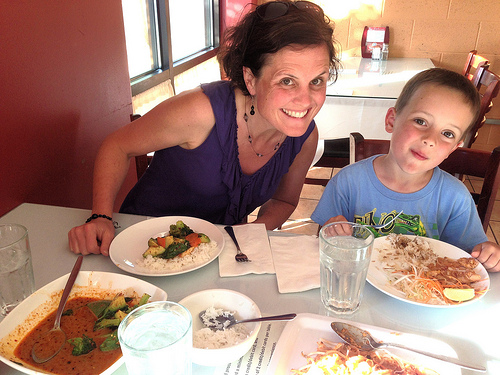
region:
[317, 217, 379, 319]
clear glass with water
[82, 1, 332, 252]
woman wearing purple top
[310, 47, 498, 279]
young boy wearing blue shirt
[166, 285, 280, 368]
white bowl of white rice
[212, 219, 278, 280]
white napkin with fork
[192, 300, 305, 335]
silver spoon with rice on it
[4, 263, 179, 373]
white bowl of green vegetables with sauce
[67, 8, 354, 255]
woman wearing necklace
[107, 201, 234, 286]
white plate with vegetables and rice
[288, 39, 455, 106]
glass covering a table top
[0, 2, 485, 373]
people sitting and eating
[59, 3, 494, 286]
the woman is leaning towards the boy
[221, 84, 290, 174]
she is wearing a necklace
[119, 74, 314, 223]
she is wearing a purple shirt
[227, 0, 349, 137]
the woman is smiling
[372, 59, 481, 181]
the boy is smiling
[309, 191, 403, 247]
the boy is holding a fork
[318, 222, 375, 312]
a glass of water on the table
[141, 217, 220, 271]
food on the woman's plate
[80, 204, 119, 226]
the woman is wearing a bracelet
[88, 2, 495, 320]
Mother and son eating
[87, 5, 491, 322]
Family at a restaurant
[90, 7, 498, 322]
Eating out with the family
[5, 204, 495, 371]
Food at a restaurant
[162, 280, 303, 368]
Bowl of rice at a restaurant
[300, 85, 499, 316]
Boy eating at a restaurant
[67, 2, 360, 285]
Woman eating at restaurant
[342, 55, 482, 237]
Little boy in a blue shirt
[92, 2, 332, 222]
Woman in a purple shirt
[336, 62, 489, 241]
Kid with their mouth fool of food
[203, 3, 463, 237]
both are focused on the camera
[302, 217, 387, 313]
glass with full of water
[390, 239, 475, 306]
some eatables with the plate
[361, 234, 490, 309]
a white color plate with circle shape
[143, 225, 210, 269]
a white color plate with some servings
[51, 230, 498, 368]
plate,cup and bowls are kept in a dining table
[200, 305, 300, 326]
a steel spoon kept in a bowl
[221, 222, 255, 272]
a fork kept in a napkin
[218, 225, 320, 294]
napkins kept above the table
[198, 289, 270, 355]
cup with rice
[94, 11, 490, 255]
woman and young boy posing for camera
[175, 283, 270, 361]
small serving bowl half empty of rice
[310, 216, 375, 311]
large glass of drinking water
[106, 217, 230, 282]
plate with vegetables and rice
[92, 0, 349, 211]
middle aged or older woman smiling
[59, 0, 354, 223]
woman wearing sleeveless purple top with ruffles around neckline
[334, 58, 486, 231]
brown eyed boy with short brown hair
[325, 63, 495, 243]
young boy at table wearing blue tshirt with head of dragon on front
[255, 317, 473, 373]
serving dish with either very thin noodles or sprouts or other kind of thinly cut vegetables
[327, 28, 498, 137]
empty table behind boy with white table cloth under clear table top